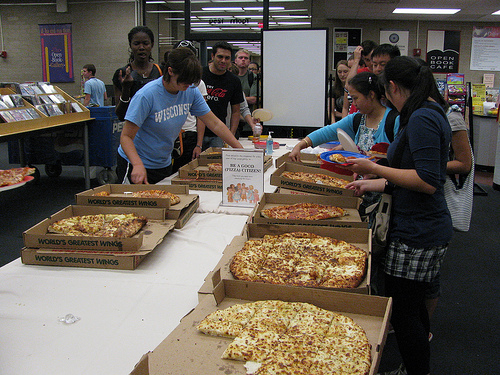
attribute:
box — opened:
[22, 204, 166, 251]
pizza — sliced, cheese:
[205, 297, 371, 374]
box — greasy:
[126, 277, 393, 374]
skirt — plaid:
[384, 236, 447, 284]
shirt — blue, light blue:
[117, 74, 212, 170]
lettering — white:
[154, 101, 190, 123]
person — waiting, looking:
[234, 49, 262, 135]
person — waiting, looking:
[198, 41, 243, 150]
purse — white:
[444, 105, 476, 233]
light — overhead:
[394, 8, 462, 15]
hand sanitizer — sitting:
[266, 130, 276, 153]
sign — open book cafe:
[426, 28, 461, 73]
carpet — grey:
[2, 177, 99, 263]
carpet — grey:
[374, 181, 500, 370]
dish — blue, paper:
[321, 150, 375, 167]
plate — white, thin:
[337, 128, 359, 154]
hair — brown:
[161, 47, 202, 88]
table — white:
[2, 137, 321, 374]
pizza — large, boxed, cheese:
[230, 231, 370, 287]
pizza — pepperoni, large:
[260, 199, 348, 222]